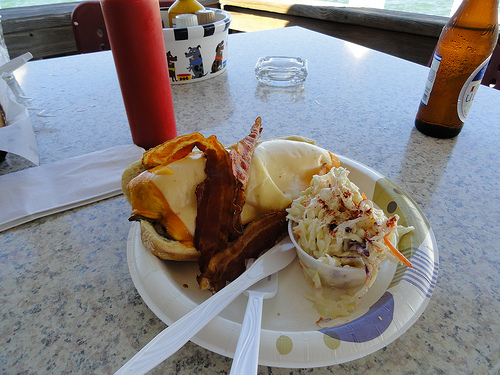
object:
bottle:
[416, 1, 500, 139]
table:
[4, 26, 500, 375]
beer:
[413, 26, 497, 139]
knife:
[113, 235, 298, 374]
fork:
[103, 241, 299, 374]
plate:
[126, 150, 440, 371]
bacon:
[139, 117, 294, 298]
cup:
[287, 216, 398, 289]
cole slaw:
[284, 166, 417, 320]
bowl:
[159, 8, 231, 85]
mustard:
[167, 0, 214, 27]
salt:
[172, 14, 199, 28]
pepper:
[195, 8, 215, 25]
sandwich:
[119, 135, 342, 262]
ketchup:
[101, 0, 180, 147]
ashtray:
[254, 55, 309, 86]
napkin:
[0, 143, 146, 231]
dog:
[184, 44, 209, 78]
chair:
[71, 0, 166, 57]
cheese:
[148, 139, 332, 233]